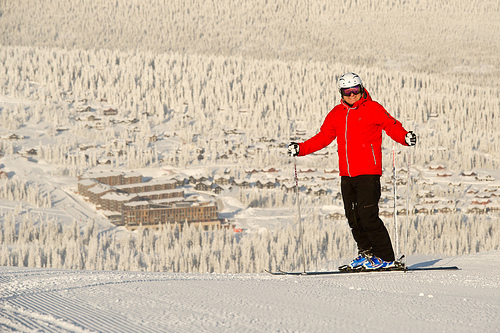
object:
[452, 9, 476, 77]
trees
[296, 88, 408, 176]
jacket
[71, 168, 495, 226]
town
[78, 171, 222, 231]
buildings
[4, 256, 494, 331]
snow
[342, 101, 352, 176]
zippers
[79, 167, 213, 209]
snow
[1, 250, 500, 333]
mountain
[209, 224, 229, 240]
tree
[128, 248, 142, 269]
tree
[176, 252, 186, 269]
tree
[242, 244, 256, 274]
tree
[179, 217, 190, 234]
tree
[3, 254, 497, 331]
ground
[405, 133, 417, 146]
glove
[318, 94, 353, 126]
ground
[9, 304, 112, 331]
straight lines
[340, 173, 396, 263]
pants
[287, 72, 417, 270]
person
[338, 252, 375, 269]
ski boots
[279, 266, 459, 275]
skis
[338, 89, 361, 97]
glasses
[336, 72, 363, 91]
helmet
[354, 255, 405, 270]
ski boots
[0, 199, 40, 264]
trees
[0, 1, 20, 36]
snow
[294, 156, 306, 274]
pole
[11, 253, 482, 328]
mountaintop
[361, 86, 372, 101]
hood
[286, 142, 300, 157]
hand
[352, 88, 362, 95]
eyes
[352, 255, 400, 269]
feet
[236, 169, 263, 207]
tree